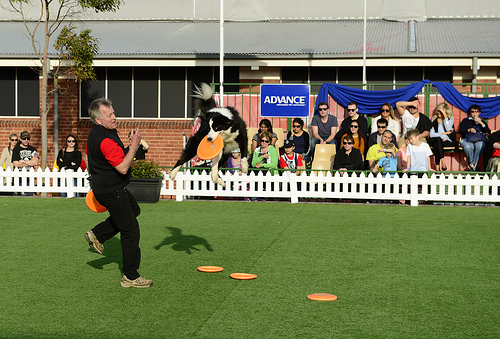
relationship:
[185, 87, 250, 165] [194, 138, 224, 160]
dog catching frisbee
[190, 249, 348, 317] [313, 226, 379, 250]
frisbees on ground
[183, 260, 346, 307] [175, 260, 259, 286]
three frisbees ground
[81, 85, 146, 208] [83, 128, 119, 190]
man wearing vest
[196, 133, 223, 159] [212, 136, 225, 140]
flying disc in mouth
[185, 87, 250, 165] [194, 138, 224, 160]
dog with frisbee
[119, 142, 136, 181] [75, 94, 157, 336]
arms of man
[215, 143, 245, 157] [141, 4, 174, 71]
jumping in air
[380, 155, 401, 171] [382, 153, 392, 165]
boy wearing shirt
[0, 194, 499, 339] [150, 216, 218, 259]
grass has shadow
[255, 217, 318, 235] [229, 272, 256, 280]
grass has frisbees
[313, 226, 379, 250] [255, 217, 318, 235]
ground has grass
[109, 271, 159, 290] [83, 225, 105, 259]
shoe on foot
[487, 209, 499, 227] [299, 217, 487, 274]
edge of field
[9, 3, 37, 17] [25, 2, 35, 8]
tree has leaves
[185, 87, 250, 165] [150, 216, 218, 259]
dog has shadow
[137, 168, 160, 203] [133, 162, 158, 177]
planter has flowers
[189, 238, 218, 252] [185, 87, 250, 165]
shadow of dog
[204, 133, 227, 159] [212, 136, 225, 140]
flying disc in mouth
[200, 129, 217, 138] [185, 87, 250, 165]
mouth of dog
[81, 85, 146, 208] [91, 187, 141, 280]
man with jeans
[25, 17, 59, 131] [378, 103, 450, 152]
background has people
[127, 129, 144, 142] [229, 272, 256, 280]
holding a frisbees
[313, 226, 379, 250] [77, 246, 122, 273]
ground has shadow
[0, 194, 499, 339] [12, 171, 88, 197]
grass has fence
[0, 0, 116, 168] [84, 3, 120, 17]
tree has leaves